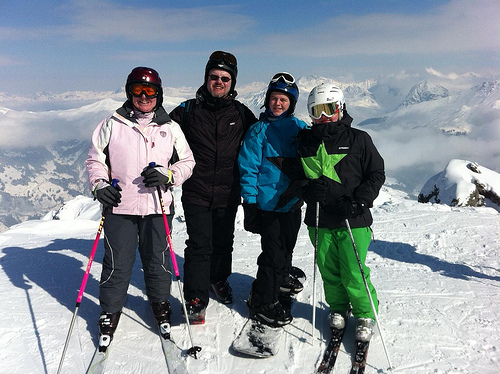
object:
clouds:
[3, 0, 497, 98]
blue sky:
[0, 2, 497, 97]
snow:
[0, 192, 497, 372]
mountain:
[0, 155, 500, 372]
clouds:
[361, 120, 491, 200]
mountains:
[1, 57, 498, 222]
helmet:
[266, 70, 300, 95]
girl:
[238, 71, 309, 326]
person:
[83, 64, 197, 352]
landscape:
[0, 0, 498, 225]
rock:
[418, 158, 500, 208]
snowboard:
[232, 265, 307, 359]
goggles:
[130, 87, 160, 99]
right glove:
[91, 181, 122, 207]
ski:
[312, 285, 379, 372]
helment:
[305, 83, 347, 119]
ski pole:
[156, 183, 203, 360]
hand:
[140, 161, 173, 187]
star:
[299, 141, 344, 188]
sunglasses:
[207, 72, 234, 82]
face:
[206, 62, 235, 99]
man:
[169, 50, 254, 324]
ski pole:
[311, 200, 323, 338]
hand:
[92, 179, 123, 209]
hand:
[301, 178, 327, 202]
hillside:
[1, 190, 498, 370]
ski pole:
[344, 218, 398, 372]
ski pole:
[55, 177, 118, 372]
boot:
[184, 281, 210, 327]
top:
[4, 46, 490, 372]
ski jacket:
[166, 88, 260, 211]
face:
[128, 81, 158, 111]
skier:
[292, 82, 387, 344]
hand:
[332, 197, 361, 222]